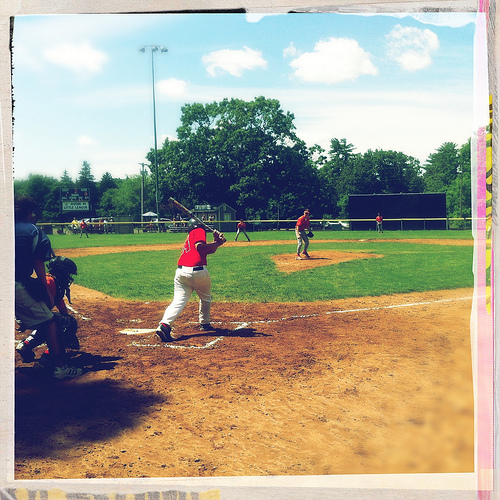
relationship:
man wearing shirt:
[155, 216, 228, 342] [176, 227, 207, 267]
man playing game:
[155, 216, 228, 342] [14, 196, 471, 381]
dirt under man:
[14, 239, 475, 480] [155, 216, 228, 342]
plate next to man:
[118, 328, 156, 336] [155, 216, 228, 342]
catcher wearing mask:
[15, 256, 80, 367] [47, 256, 78, 290]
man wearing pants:
[155, 216, 228, 342] [159, 265, 212, 326]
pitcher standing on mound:
[294, 209, 315, 261] [269, 250, 385, 274]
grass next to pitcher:
[44, 229, 491, 304] [294, 209, 315, 261]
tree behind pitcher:
[144, 95, 310, 226] [294, 209, 315, 261]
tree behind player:
[95, 187, 141, 217] [234, 218, 251, 242]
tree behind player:
[418, 142, 460, 193] [375, 211, 385, 234]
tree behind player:
[75, 159, 100, 205] [78, 218, 90, 239]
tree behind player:
[334, 158, 382, 197] [155, 216, 228, 342]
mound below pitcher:
[269, 250, 385, 274] [294, 209, 315, 261]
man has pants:
[155, 216, 228, 342] [159, 265, 212, 326]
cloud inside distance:
[200, 45, 268, 79] [13, 12, 473, 260]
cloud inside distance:
[288, 37, 378, 84] [13, 12, 473, 260]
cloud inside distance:
[382, 23, 439, 72] [13, 12, 473, 260]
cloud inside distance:
[154, 77, 190, 100] [13, 12, 473, 260]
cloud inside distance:
[44, 40, 108, 76] [13, 12, 473, 260]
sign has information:
[59, 187, 93, 235] [60, 187, 91, 211]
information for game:
[60, 187, 91, 211] [14, 196, 471, 381]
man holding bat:
[155, 216, 228, 342] [167, 196, 227, 244]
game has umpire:
[14, 196, 471, 381] [15, 194, 83, 380]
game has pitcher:
[14, 196, 471, 381] [294, 209, 315, 261]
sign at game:
[59, 187, 93, 235] [14, 196, 471, 381]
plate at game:
[118, 328, 156, 336] [14, 196, 471, 381]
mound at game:
[269, 250, 385, 274] [14, 196, 471, 381]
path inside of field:
[65, 295, 473, 350] [14, 217, 473, 480]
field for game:
[14, 217, 473, 480] [14, 196, 471, 381]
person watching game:
[70, 217, 80, 229] [14, 196, 471, 381]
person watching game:
[103, 216, 110, 234] [14, 196, 471, 381]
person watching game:
[98, 218, 105, 230] [14, 196, 471, 381]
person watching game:
[208, 211, 216, 225] [14, 196, 471, 381]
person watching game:
[200, 214, 208, 222] [14, 196, 471, 381]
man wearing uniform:
[155, 216, 228, 342] [159, 227, 212, 329]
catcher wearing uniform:
[15, 256, 80, 367] [23, 255, 78, 355]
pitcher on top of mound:
[294, 209, 315, 261] [269, 250, 385, 274]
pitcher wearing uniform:
[294, 209, 315, 261] [294, 215, 310, 254]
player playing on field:
[234, 218, 251, 242] [14, 217, 473, 480]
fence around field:
[35, 217, 471, 235] [14, 217, 473, 480]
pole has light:
[137, 44, 168, 233] [138, 47, 146, 55]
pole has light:
[137, 44, 168, 233] [150, 46, 160, 54]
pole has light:
[137, 44, 168, 233] [160, 47, 168, 53]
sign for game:
[59, 187, 93, 235] [14, 196, 471, 381]